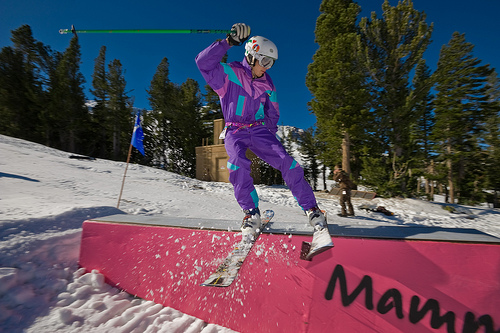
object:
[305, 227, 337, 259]
ski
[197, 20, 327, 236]
person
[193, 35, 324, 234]
woman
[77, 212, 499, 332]
ramp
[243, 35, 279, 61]
helmet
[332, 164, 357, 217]
person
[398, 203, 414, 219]
snow